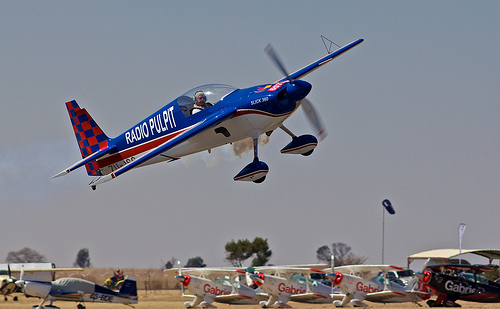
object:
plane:
[162, 268, 266, 309]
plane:
[252, 261, 329, 306]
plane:
[325, 259, 430, 307]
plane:
[163, 249, 500, 309]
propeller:
[264, 43, 328, 140]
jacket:
[102, 277, 125, 291]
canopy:
[405, 249, 499, 272]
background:
[0, 0, 499, 255]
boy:
[368, 29, 472, 153]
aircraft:
[0, 249, 500, 309]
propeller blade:
[259, 39, 294, 84]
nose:
[249, 78, 311, 118]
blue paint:
[233, 161, 269, 184]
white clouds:
[201, 140, 273, 163]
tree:
[223, 236, 272, 267]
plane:
[233, 254, 308, 306]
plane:
[299, 261, 406, 306]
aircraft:
[51, 34, 365, 190]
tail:
[64, 99, 117, 177]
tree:
[182, 256, 205, 267]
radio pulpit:
[123, 105, 177, 144]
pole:
[381, 208, 384, 265]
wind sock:
[382, 199, 396, 215]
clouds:
[0, 0, 473, 251]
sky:
[0, 0, 500, 248]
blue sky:
[0, 5, 500, 262]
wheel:
[253, 175, 267, 183]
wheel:
[301, 148, 314, 156]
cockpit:
[185, 82, 258, 137]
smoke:
[231, 133, 268, 158]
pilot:
[190, 90, 215, 116]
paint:
[141, 86, 271, 158]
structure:
[0, 267, 134, 309]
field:
[0, 254, 500, 309]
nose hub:
[284, 80, 312, 101]